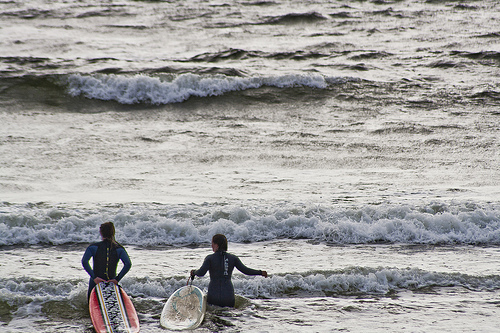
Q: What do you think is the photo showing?
A: It is showing an ocean.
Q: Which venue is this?
A: This is an ocean.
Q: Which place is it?
A: It is an ocean.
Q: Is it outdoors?
A: Yes, it is outdoors.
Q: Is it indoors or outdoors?
A: It is outdoors.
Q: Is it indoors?
A: No, it is outdoors.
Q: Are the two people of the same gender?
A: Yes, all the people are female.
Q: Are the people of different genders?
A: No, all the people are female.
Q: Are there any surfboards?
A: Yes, there is a surfboard.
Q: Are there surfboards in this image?
A: Yes, there is a surfboard.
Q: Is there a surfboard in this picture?
A: Yes, there is a surfboard.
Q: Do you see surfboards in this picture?
A: Yes, there is a surfboard.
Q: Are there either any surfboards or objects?
A: Yes, there is a surfboard.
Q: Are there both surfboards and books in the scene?
A: No, there is a surfboard but no books.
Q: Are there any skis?
A: No, there are no skis.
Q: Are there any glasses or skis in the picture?
A: No, there are no skis or glasses.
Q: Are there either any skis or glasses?
A: No, there are no skis or glasses.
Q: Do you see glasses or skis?
A: No, there are no skis or glasses.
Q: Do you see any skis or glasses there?
A: No, there are no skis or glasses.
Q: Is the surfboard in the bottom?
A: Yes, the surfboard is in the bottom of the image.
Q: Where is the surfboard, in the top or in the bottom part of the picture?
A: The surfboard is in the bottom of the image.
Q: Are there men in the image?
A: No, there are no men.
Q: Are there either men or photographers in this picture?
A: No, there are no men or photographers.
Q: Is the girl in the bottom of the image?
A: Yes, the girl is in the bottom of the image.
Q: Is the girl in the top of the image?
A: No, the girl is in the bottom of the image.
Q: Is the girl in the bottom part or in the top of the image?
A: The girl is in the bottom of the image.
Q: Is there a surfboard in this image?
A: Yes, there is a surfboard.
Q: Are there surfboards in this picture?
A: Yes, there is a surfboard.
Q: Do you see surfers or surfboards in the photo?
A: Yes, there is a surfboard.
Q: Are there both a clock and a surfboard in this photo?
A: No, there is a surfboard but no clocks.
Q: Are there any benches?
A: No, there are no benches.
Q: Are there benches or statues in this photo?
A: No, there are no benches or statues.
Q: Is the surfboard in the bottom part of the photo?
A: Yes, the surfboard is in the bottom of the image.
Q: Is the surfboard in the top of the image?
A: No, the surfboard is in the bottom of the image.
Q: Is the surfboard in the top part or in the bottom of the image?
A: The surfboard is in the bottom of the image.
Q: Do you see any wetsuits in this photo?
A: Yes, there is a wetsuit.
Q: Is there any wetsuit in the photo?
A: Yes, there is a wetsuit.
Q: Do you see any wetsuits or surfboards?
A: Yes, there is a wetsuit.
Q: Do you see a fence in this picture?
A: No, there are no fences.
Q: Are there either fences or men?
A: No, there are no fences or men.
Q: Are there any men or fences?
A: No, there are no fences or men.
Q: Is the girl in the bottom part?
A: Yes, the girl is in the bottom of the image.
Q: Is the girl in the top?
A: No, the girl is in the bottom of the image.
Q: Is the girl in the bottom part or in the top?
A: The girl is in the bottom of the image.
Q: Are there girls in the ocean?
A: Yes, there is a girl in the ocean.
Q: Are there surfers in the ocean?
A: No, there is a girl in the ocean.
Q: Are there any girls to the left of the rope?
A: Yes, there is a girl to the left of the rope.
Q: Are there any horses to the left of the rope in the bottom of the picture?
A: No, there is a girl to the left of the rope.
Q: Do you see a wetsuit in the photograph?
A: Yes, there is a wetsuit.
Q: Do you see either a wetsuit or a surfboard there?
A: Yes, there is a wetsuit.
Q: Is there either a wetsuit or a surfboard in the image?
A: Yes, there is a wetsuit.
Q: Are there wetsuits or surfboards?
A: Yes, there is a wetsuit.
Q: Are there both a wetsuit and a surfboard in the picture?
A: Yes, there are both a wetsuit and a surfboard.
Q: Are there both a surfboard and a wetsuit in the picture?
A: Yes, there are both a wetsuit and a surfboard.